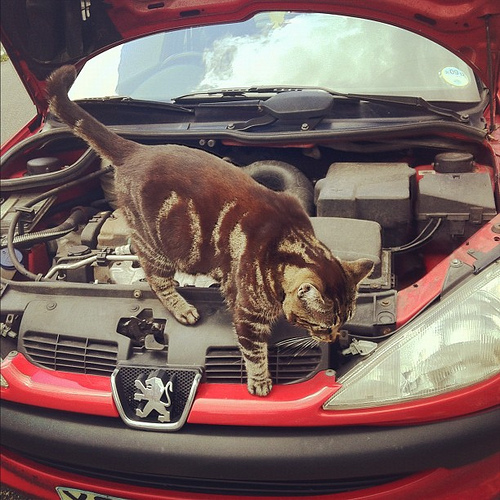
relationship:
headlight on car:
[313, 253, 499, 414] [3, 1, 496, 498]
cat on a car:
[40, 60, 374, 394] [3, 1, 496, 498]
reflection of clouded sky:
[191, 10, 483, 102] [66, 10, 481, 105]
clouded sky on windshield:
[66, 10, 481, 105] [68, 10, 483, 101]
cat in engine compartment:
[40, 64, 374, 397] [0, 126, 500, 295]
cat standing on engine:
[40, 64, 374, 397] [8, 141, 484, 279]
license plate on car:
[49, 476, 142, 496] [17, 71, 493, 493]